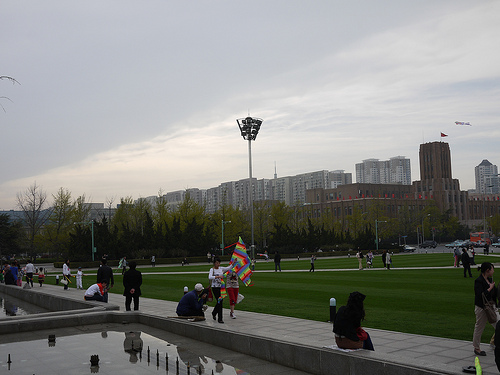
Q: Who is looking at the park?
A: The photorapher.